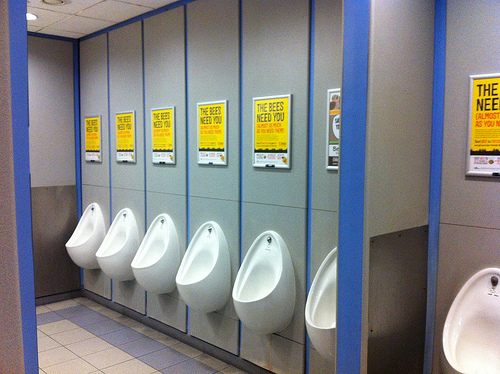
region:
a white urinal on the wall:
[63, 200, 107, 270]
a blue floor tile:
[36, 308, 65, 325]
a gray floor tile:
[37, 317, 80, 335]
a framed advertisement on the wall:
[251, 92, 294, 171]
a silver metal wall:
[31, 183, 86, 305]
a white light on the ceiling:
[24, 11, 38, 23]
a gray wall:
[26, 35, 75, 187]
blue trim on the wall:
[6, 0, 43, 371]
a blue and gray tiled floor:
[33, 295, 245, 372]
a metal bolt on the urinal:
[265, 235, 272, 245]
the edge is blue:
[334, 6, 368, 327]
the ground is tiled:
[51, 304, 119, 371]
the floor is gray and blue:
[47, 301, 140, 371]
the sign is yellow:
[143, 102, 186, 174]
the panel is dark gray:
[362, 215, 434, 372]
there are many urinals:
[59, 179, 366, 363]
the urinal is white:
[229, 227, 306, 342]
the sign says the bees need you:
[242, 83, 300, 192]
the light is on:
[13, 2, 46, 32]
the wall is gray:
[43, 61, 70, 171]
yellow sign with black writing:
[248, 95, 303, 180]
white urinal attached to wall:
[173, 216, 228, 335]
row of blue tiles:
[58, 300, 243, 371]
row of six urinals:
[42, 173, 362, 369]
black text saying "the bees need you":
[251, 98, 296, 122]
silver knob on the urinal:
[262, 230, 278, 246]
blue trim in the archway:
[332, 2, 370, 369]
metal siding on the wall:
[26, 177, 89, 305]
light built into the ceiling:
[16, 3, 44, 35]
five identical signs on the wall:
[66, 103, 289, 178]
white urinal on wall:
[65, 200, 103, 271]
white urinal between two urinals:
[95, 207, 140, 277]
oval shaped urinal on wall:
[125, 211, 176, 296]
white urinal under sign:
[172, 220, 232, 310]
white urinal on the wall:
[227, 227, 293, 329]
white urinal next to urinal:
[305, 235, 335, 360]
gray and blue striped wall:
[71, 0, 341, 370]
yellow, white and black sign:
[80, 111, 100, 161]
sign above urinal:
[111, 107, 132, 162]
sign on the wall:
[147, 103, 172, 166]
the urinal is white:
[167, 214, 245, 331]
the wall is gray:
[145, 23, 175, 90]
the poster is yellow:
[245, 83, 305, 185]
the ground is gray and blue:
[112, 332, 199, 371]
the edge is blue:
[11, 114, 53, 367]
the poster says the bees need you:
[247, 90, 297, 180]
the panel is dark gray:
[23, 165, 117, 310]